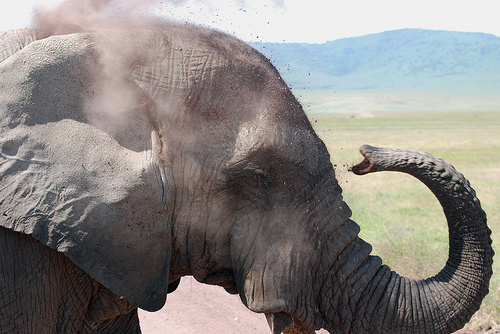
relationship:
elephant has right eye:
[2, 24, 496, 334] [225, 169, 266, 190]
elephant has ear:
[2, 24, 496, 334] [2, 31, 174, 314]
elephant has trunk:
[2, 24, 496, 334] [303, 139, 494, 334]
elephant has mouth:
[2, 24, 496, 334] [227, 232, 319, 334]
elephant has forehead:
[2, 24, 496, 334] [207, 28, 322, 142]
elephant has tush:
[2, 24, 496, 334] [263, 309, 297, 334]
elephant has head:
[2, 24, 496, 334] [102, 21, 321, 332]